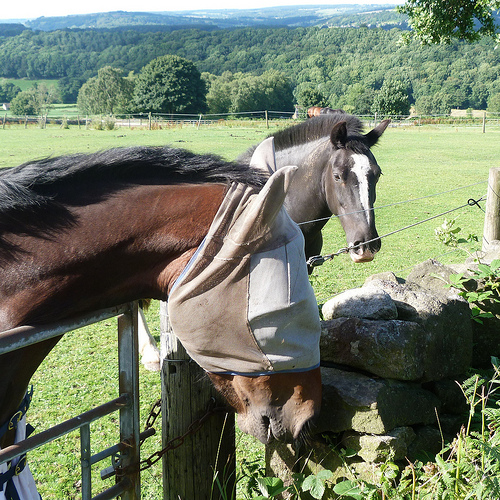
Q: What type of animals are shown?
A: Horses.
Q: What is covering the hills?
A: Trees.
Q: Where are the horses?
A: Field.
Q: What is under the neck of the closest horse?
A: Fence.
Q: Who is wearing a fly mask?
A: Nearest horse.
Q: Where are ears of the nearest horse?
A: Under fly mask.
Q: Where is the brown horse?
A: Nearest the camera.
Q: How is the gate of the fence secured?
A: Chain.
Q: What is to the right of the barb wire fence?
A: Stack of rocks.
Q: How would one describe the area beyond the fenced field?
A: Wooded.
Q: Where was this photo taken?
A: A pasture.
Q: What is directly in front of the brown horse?
A: A gate.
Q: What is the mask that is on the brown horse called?
A: Fly mask.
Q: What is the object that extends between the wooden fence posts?
A: Cables.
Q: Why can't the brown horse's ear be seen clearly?
A: Horse is wearing a mask.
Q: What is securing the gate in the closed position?
A: A chain and a padlock.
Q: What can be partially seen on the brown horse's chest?
A: Blanket with buckles.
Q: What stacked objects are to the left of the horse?
A: Stones.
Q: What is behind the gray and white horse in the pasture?
A: Another horse.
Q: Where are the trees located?
A: Behind the fence.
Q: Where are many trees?
A: In the distance.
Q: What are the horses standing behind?
A: A fence.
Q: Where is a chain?
A: On the fence.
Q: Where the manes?
A: On horse's necks.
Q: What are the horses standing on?
A: Grass.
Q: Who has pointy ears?
A: The horses.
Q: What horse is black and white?
A: Horse on right.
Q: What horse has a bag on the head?
A: Horse on left.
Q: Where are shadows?
A: On large rocks.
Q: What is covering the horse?
A: Cloth.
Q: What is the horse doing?
A: Eating.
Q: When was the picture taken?
A: During the day.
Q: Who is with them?
A: No one.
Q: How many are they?
A: 3.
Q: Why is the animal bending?
A: To eat.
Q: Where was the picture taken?
A: A field.